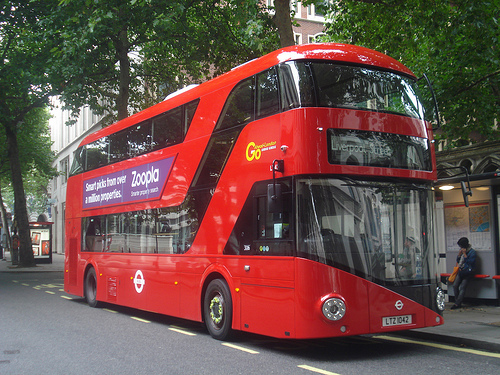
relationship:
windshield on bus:
[295, 178, 436, 283] [64, 44, 448, 341]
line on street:
[298, 363, 339, 374] [0, 270, 498, 374]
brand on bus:
[133, 270, 145, 294] [64, 44, 448, 341]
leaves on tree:
[0, 0, 58, 119] [1, 0, 58, 269]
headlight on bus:
[323, 298, 345, 321] [64, 44, 448, 341]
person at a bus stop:
[450, 236, 485, 309] [433, 171, 497, 309]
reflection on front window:
[391, 74, 425, 119] [256, 59, 423, 116]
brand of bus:
[130, 269, 147, 294] [64, 44, 448, 341]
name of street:
[330, 136, 368, 153] [0, 270, 498, 374]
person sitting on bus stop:
[450, 236, 485, 309] [433, 171, 497, 309]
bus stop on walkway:
[433, 171, 497, 309] [414, 299, 497, 349]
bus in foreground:
[64, 44, 448, 341] [3, 264, 498, 374]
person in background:
[0, 225, 11, 254] [1, 0, 499, 267]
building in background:
[23, 96, 118, 261] [1, 0, 499, 267]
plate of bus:
[382, 314, 414, 327] [64, 44, 448, 341]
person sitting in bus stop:
[450, 236, 485, 309] [433, 171, 497, 309]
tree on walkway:
[1, 0, 58, 269] [2, 252, 65, 270]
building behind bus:
[23, 96, 118, 261] [64, 44, 448, 341]